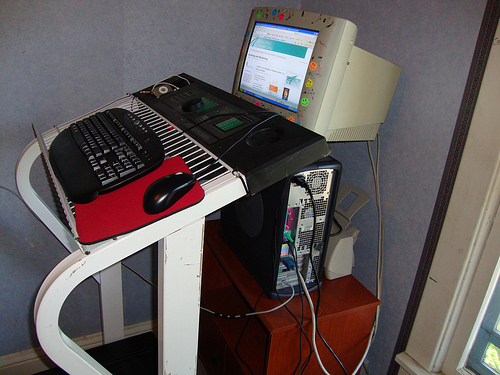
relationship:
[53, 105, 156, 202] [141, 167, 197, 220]
keyboard near mouse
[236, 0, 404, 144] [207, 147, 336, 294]
monitor above tower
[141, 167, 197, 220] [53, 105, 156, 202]
mouse near keyboard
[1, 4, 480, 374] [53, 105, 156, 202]
wall behind keyboard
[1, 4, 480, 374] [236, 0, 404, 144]
wall behind monitor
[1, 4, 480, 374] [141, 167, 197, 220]
wall behind mouse